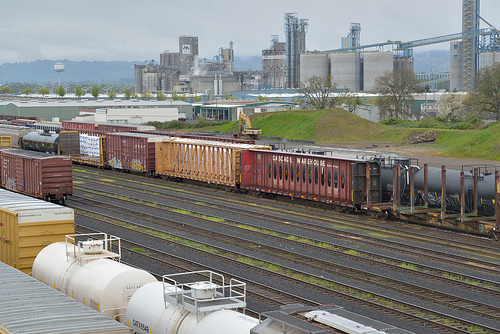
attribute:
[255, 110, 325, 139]
grass — green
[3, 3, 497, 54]
sky — gray, cloudy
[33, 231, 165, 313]
tank — white, black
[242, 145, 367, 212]
carrier — red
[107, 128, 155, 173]
container — maroon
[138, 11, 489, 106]
plant — gray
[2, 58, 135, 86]
mountain — distant, blue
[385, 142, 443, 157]
soil — brown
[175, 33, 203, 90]
building — tall, grey, white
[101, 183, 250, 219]
tracks — black, empty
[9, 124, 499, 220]
train — cargo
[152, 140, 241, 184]
car — orange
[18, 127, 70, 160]
tank — black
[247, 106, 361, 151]
hill — green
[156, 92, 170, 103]
tree — green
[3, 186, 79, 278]
car — yellow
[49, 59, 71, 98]
tower — white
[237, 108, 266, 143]
backhoe — yellow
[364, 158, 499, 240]
car — rusted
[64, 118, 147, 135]
car — red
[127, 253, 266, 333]
tanker — white